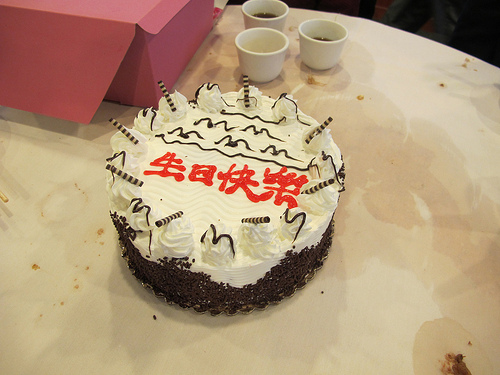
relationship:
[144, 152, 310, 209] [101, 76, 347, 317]
characters on cake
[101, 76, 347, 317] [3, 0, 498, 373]
cake on table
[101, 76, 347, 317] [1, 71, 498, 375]
cake on table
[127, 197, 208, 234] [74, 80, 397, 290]
candle on cake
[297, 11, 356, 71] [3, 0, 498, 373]
cup on table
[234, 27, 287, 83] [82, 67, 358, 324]
cup behind cake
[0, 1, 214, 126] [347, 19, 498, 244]
box on table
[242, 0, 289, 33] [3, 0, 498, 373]
cup on table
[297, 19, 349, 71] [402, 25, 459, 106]
cup on table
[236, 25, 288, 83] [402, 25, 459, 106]
cup on table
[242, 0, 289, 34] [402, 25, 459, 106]
cup on table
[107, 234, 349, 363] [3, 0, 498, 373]
shadow on table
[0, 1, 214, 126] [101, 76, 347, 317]
box next to cake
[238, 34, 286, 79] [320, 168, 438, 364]
bowl on table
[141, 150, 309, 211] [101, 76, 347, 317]
frosting on cake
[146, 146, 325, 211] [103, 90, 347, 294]
characters on cake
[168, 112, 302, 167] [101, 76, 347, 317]
icing on top of cake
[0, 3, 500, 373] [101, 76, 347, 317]
tablecloth under cake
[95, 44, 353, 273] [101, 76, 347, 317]
candles on cake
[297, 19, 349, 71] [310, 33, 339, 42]
cup with liquid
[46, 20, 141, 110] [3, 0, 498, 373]
box on table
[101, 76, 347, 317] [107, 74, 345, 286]
cake with icing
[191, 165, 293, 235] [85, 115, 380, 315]
icing on cake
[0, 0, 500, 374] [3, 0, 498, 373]
shadow on table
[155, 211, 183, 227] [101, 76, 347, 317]
biscuit stick on cake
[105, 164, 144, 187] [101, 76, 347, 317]
biscuit stick on cake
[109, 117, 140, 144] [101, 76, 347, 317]
biscuit stick on cake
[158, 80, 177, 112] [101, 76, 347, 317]
biscuit stick on cake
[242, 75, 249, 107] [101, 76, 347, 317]
biscuit stick on cake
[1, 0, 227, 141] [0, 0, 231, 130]
lid of box